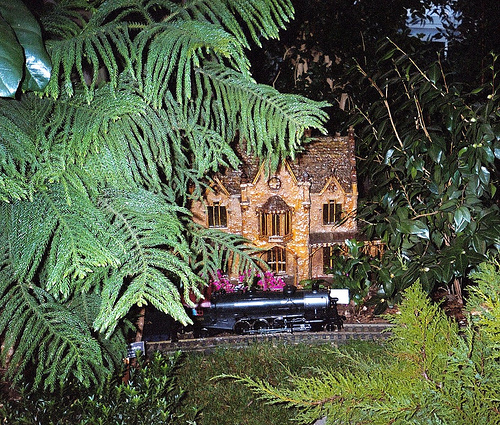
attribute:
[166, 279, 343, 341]
train — black, toy, model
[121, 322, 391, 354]
tracks — model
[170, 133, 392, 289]
house — brick, brown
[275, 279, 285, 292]
flower — pink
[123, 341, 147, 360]
sign — small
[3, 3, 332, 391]
tree — green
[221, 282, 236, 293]
flower — pink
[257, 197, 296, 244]
window — upstairs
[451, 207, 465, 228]
leaf — plastic looking, green, smooth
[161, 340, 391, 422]
grass — short